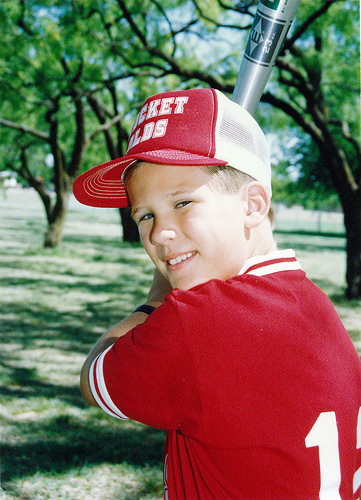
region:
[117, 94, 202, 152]
words on a baseball hat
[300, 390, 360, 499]
number on the back of a shirt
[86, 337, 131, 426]
stripes on a shirt sleeve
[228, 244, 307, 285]
collar on a boy's shirt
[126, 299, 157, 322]
black band on the boy's left hand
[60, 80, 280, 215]
red and white baseball cap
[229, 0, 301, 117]
silver aluminum baseball bat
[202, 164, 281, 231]
boy's blond hair under the cap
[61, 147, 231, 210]
red bill of the cap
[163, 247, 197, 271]
smile showing white teeth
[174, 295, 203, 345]
part of the red shirt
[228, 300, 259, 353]
part of the red shirt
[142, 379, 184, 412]
part of the red shirt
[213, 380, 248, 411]
part of the red shirt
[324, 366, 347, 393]
part of the red shirt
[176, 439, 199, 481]
part of the red shirt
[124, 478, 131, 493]
part of a grass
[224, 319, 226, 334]
part of a neck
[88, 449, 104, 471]
part of a grass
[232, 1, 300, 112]
aluminum baseball bat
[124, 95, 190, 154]
white writing on red hat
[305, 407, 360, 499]
white numbers on back of jersey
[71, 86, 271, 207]
red and white baseball cap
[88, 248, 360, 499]
red baseball jersey with white trim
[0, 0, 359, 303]
three trees standing behind baseball player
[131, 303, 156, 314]
black tape on left wrist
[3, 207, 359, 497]
grass beneath trees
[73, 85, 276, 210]
a red and white ball cap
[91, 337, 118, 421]
a white strip on a selve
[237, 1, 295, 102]
a gray metal bat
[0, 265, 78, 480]
shadows on the ground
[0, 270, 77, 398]
shadows of trees on the ground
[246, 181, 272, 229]
a left ear on a boy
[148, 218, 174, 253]
a nose on a boy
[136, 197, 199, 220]
eyes on a boy